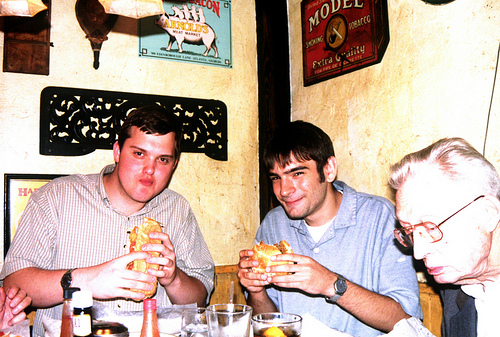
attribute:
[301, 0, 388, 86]
sign — model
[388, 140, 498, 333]
man — older, old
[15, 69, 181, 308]
man — smiling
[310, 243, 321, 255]
button — white, blue, checked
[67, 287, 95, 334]
bottle — steak sauce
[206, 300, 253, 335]
glass — drinking, empty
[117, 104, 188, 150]
hair — short, dark colored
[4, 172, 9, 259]
black frame — black 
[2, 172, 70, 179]
black frame — black 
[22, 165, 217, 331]
shirt — button up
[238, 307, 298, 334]
glass — drinking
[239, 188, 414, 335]
shirt — blue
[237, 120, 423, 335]
man — young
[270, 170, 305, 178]
eyes — brown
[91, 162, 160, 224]
collar — open